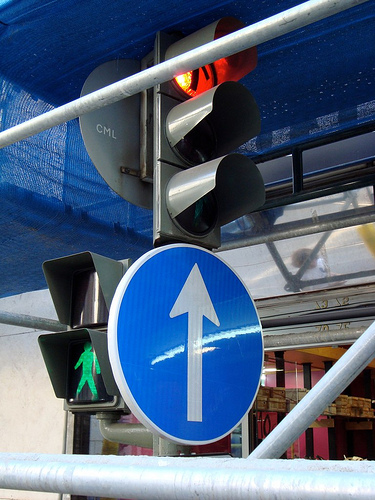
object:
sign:
[78, 60, 152, 208]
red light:
[174, 55, 238, 103]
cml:
[96, 123, 116, 139]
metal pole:
[0, 451, 374, 500]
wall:
[3, 338, 35, 447]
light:
[38, 328, 121, 405]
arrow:
[169, 262, 221, 422]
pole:
[211, 210, 375, 254]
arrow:
[189, 66, 209, 92]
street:
[0, 288, 374, 499]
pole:
[247, 321, 375, 458]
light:
[166, 81, 261, 165]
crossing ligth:
[74, 342, 101, 402]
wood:
[254, 385, 374, 419]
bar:
[0, 1, 370, 150]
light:
[165, 152, 266, 238]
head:
[84, 342, 92, 352]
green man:
[74, 343, 101, 402]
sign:
[106, 241, 264, 445]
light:
[165, 19, 259, 98]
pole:
[97, 413, 155, 449]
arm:
[74, 353, 83, 370]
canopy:
[0, 0, 375, 301]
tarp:
[0, 5, 370, 300]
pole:
[151, 244, 191, 456]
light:
[41, 251, 124, 329]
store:
[246, 347, 375, 458]